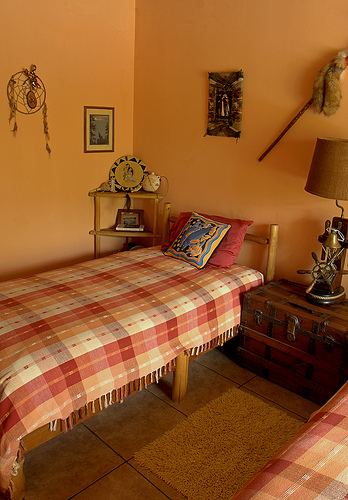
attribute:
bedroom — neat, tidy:
[1, 0, 347, 498]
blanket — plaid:
[229, 378, 345, 498]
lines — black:
[70, 418, 163, 498]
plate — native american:
[105, 155, 146, 192]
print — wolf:
[79, 104, 118, 155]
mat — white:
[136, 385, 306, 498]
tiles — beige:
[43, 438, 119, 498]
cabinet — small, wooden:
[91, 182, 164, 255]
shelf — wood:
[72, 146, 162, 249]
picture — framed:
[65, 101, 148, 157]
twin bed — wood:
[88, 195, 283, 408]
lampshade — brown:
[303, 136, 347, 201]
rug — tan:
[135, 393, 295, 490]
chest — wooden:
[240, 273, 346, 397]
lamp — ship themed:
[297, 138, 347, 305]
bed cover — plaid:
[5, 236, 209, 388]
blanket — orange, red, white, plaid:
[0, 235, 277, 484]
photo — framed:
[95, 197, 160, 237]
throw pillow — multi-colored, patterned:
[164, 211, 231, 267]